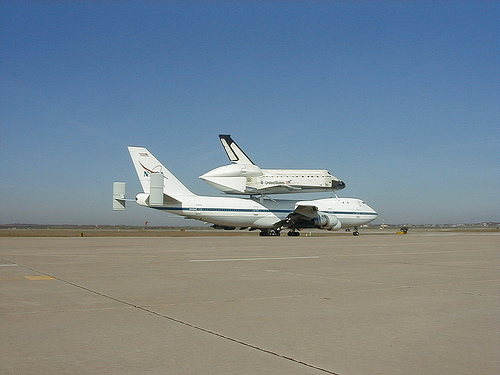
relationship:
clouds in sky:
[382, 98, 473, 198] [2, 0, 498, 217]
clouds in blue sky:
[25, 125, 105, 213] [1, 0, 498, 227]